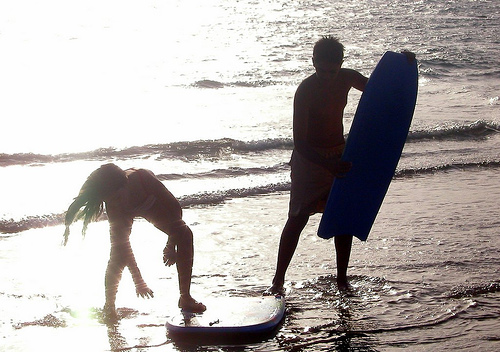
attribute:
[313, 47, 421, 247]
board — blue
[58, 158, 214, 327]
girl — reachig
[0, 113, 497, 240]
waves — crashing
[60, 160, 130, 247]
hair — wet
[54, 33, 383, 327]
boy and girl — silhouettes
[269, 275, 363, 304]
feet — wet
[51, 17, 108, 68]
bear — white